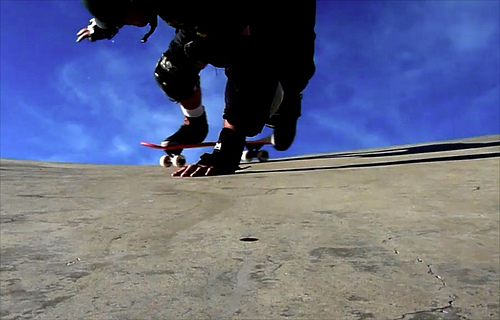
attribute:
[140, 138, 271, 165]
skateboard — red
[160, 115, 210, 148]
foot — black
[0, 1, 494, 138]
blue sky — bright blue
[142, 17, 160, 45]
chinstrap — loose